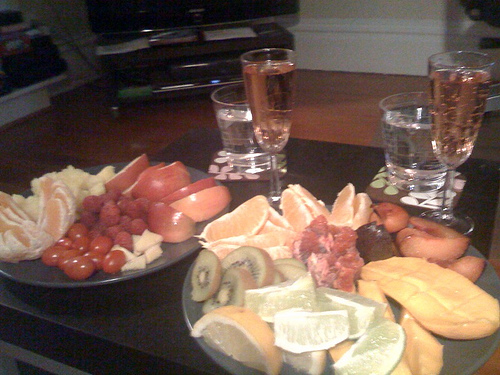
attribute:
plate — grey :
[203, 184, 484, 364]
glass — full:
[378, 88, 454, 193]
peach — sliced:
[396, 212, 469, 262]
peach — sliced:
[373, 198, 410, 231]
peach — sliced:
[443, 253, 487, 283]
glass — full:
[402, 34, 497, 241]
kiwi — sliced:
[194, 269, 248, 304]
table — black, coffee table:
[6, 120, 494, 374]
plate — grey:
[182, 204, 497, 374]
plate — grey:
[142, 146, 487, 373]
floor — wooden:
[255, 56, 454, 165]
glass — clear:
[380, 87, 447, 193]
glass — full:
[240, 48, 300, 206]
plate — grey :
[0, 167, 232, 291]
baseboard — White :
[298, 13, 428, 82]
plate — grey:
[0, 160, 241, 301]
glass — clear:
[232, 39, 299, 210]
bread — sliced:
[350, 267, 479, 338]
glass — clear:
[173, 82, 277, 206]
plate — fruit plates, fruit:
[1, 151, 223, 292]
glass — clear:
[384, 100, 447, 187]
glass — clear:
[428, 52, 491, 232]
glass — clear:
[246, 51, 296, 202]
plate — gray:
[182, 246, 499, 374]